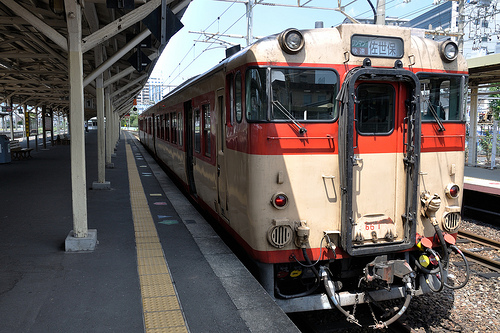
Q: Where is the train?
A: Train station.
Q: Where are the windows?
A: On the train.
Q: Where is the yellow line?
A: On the ground.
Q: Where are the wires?
A: Hanging over the train.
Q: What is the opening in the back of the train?
A: Door.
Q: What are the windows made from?
A: Glass.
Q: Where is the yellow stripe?
A: On the platform.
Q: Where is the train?
A: On the tracks.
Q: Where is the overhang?
A: On the platform.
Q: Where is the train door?
A: On the front.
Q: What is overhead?
A: Blue sky.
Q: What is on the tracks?
A: A train.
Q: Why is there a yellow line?
A: Safety.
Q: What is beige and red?
A: The train.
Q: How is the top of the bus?
A: Dirty.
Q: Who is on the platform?
A: No passengers.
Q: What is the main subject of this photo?
A: Train.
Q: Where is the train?
A: Train tracks.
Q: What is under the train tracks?
A: Gravel.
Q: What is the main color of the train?
A: Red and tan.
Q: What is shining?
A: Sun.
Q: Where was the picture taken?
A: A train station.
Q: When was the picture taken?
A: Daytime.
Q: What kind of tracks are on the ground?
A: Train tracks.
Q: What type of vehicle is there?
A: A train.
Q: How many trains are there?
A: One.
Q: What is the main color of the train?
A: Beige.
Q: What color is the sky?
A: Blue.